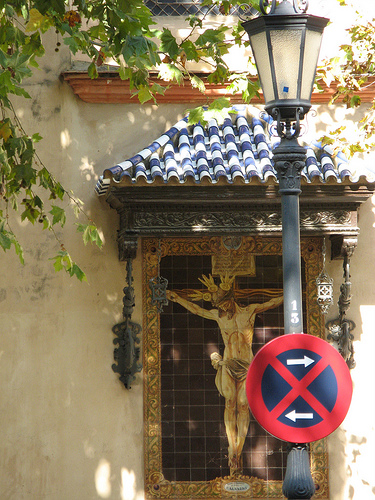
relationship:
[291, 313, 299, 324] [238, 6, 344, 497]
number on pole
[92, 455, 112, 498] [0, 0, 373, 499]
sunlight on wall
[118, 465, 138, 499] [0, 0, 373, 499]
sunlight on wall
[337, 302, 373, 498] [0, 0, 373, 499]
sunlight on wall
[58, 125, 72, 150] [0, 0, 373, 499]
sunlight on wall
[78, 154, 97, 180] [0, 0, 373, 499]
sunlight on wall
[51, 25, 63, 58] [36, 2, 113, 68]
fruits hanging from branch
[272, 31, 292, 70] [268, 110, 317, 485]
glass on stand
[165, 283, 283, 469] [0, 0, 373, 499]
jesus on wall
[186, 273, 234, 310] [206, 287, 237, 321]
thorns on head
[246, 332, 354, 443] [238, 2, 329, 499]
cross sign on a lamp pole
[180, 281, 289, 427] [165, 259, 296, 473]
jesus on cross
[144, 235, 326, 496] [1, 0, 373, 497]
sculpture on building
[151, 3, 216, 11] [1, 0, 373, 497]
roof on building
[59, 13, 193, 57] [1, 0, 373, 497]
trees hanging off building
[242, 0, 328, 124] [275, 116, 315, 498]
lamp on pole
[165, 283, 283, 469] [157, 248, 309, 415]
jesus in painting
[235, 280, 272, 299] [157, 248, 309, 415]
cross in painting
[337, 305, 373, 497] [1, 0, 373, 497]
light on building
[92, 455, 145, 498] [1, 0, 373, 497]
light on building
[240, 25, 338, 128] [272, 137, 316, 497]
lamp on a stand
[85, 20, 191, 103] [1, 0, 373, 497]
leaves near building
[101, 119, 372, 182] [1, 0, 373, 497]
tiles on a building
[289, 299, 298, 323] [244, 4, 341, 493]
number on a post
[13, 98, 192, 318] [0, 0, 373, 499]
spots on a wall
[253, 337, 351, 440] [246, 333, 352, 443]
cross sign on a sign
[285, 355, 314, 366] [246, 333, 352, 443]
arrow on a sign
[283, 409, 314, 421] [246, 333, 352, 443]
arrow on a sign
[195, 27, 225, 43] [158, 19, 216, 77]
leaves on a branch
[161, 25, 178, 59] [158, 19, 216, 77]
leaves on a branch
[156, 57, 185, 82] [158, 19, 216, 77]
leaves on a branch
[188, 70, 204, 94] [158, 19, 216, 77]
leaves on a branch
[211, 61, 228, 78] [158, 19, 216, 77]
leaves on a branch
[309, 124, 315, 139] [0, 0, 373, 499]
reflection on a wall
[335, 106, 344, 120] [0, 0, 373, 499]
reflection on a wall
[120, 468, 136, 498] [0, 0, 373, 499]
reflection on a wall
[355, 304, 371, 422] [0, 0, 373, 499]
reflection on a wall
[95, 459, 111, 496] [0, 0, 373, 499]
reflection on a wall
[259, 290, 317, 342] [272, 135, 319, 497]
numbers on a pole